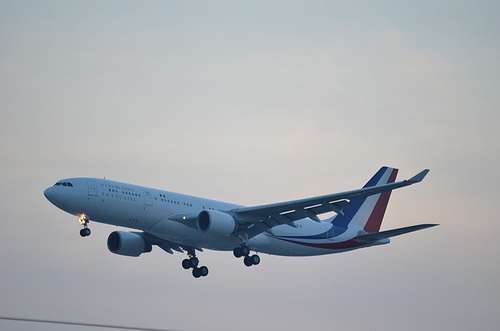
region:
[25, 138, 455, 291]
REd white and blue airplane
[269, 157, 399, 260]
Red white and blue stripes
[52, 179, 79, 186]
Small pilot window on front of plane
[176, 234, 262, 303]
Four sets of black wheels on plane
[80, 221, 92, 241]
Small black wheels on plane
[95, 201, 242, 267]
Two white engines on plane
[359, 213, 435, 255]
One small back wing on plane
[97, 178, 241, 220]
Row of windows on plane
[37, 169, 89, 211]
White nose of airplane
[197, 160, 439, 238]
one large white wing of plane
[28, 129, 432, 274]
the plane is flying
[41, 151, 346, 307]
the plane is white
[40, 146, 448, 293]
Red white and blue airplane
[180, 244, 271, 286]
Black and white wheels on airplane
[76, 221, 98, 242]
Two small black wheels on airplane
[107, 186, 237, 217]
Row of tiny white windows on airplane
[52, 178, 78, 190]
Small windows on front of airplane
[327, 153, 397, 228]
One back wing on back of airplane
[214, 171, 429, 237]
One large white wing on airplane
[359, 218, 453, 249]
Small side wing of airplane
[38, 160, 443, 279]
Plane in the air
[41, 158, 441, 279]
Plane is in the air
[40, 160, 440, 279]
Airplane in the air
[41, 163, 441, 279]
Airplane is in the air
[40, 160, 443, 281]
Plane flying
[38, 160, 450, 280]
Plane is flying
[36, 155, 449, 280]
Airplane flying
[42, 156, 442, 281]
Airplane is flying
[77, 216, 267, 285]
Landing gear on airplane is deployed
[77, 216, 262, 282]
Landing gear on plane is deployed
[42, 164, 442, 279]
a large blue jet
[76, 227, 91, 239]
two small landing wheels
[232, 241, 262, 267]
a set of four left landing wheels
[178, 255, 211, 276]
a set of four right landing wheels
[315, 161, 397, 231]
blue, red and white tail wing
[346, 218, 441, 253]
small back left wing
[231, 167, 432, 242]
a long left wing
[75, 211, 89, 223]
bright light under plane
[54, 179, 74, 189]
front windshield of plane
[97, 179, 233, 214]
a line of windows